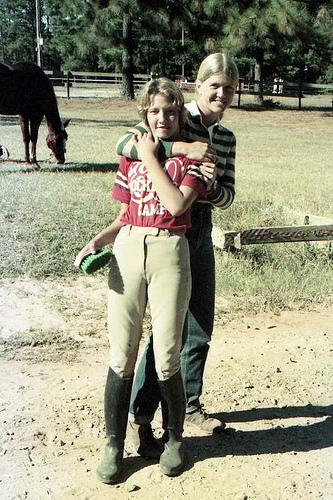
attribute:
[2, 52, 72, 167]
horse — brown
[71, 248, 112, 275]
brush — green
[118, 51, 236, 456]
girl — standing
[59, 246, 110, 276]
brush — green